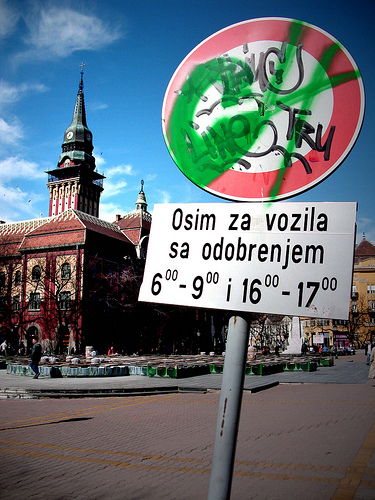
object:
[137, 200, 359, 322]
sign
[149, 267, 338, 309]
times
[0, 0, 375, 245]
sky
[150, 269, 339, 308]
numbers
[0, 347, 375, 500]
road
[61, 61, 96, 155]
dome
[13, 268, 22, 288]
window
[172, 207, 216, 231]
osim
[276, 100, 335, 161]
paint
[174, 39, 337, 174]
text black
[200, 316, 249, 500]
cow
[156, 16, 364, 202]
sign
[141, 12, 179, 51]
pink helmet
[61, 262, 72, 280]
small window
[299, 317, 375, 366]
storefronts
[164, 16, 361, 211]
graffiti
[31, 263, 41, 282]
window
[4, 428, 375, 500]
lines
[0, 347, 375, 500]
street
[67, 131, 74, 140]
clock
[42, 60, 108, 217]
tower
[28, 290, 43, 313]
window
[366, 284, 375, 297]
window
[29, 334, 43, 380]
people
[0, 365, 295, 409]
side walk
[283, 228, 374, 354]
building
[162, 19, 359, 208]
spay paint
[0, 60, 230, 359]
church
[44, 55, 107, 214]
steeple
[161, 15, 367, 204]
circular sign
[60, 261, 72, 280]
window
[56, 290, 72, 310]
window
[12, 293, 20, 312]
window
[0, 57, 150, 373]
building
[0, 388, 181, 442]
line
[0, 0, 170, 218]
cloud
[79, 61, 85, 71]
cross